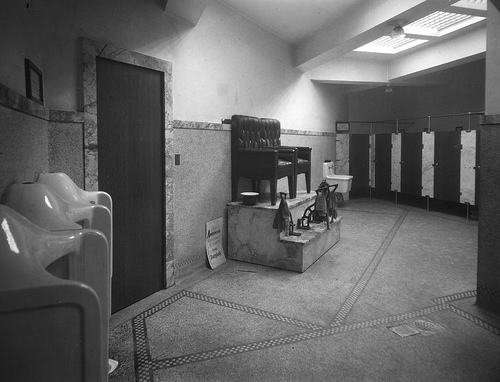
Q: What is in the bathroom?
A: The door.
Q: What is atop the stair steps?
A: The cushioned seats.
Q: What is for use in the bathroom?
A: The urinals.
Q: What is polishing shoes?
A: The seats.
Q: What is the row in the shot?
A: The closed bathroom stalls.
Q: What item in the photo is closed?
A: The door.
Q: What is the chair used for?
A: Sitting.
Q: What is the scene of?
A: Bathroom.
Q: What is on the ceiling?
A: Lights.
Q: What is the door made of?
A: Wood.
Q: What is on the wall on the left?
A: Urinals.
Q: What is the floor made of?
A: Tiles.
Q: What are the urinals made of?
A: Ceramic.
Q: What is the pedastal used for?
A: Shining shoes.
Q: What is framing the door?
A: Marble tiles.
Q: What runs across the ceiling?
A: Beams.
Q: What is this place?
A: A men's restroom.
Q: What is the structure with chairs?
A: A shoe-shine stand.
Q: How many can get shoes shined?
A: 2.